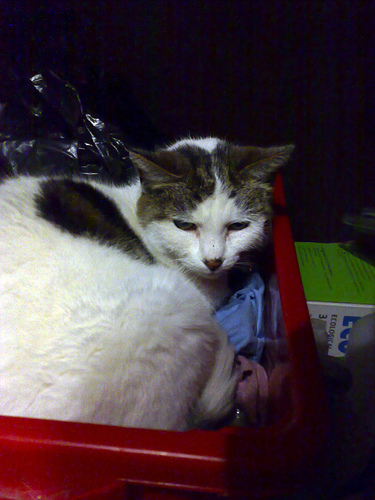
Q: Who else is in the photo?
A: Nobody.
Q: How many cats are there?
A: One.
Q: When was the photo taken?
A: Nighttime.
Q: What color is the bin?
A: Red.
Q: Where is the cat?
A: In the bin.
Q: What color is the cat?
A: White.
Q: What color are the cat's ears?
A: Black and gold.